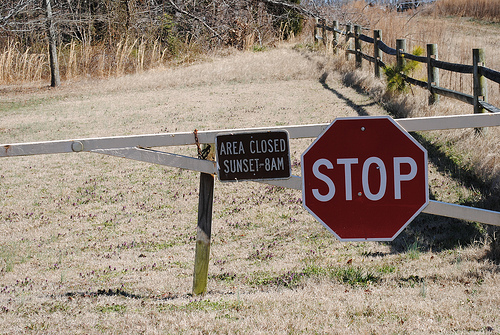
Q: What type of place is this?
A: It is a park.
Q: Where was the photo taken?
A: It was taken at the park.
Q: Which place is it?
A: It is a park.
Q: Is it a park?
A: Yes, it is a park.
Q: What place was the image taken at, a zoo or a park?
A: It was taken at a park.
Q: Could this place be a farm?
A: No, it is a park.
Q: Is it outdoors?
A: Yes, it is outdoors.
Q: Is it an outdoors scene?
A: Yes, it is outdoors.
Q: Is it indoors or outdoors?
A: It is outdoors.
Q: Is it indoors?
A: No, it is outdoors.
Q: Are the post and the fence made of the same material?
A: Yes, both the post and the fence are made of wood.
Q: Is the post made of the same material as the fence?
A: Yes, both the post and the fence are made of wood.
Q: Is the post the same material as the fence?
A: Yes, both the post and the fence are made of wood.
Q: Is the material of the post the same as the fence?
A: Yes, both the post and the fence are made of wood.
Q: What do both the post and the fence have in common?
A: The material, both the post and the fence are wooden.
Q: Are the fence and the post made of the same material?
A: Yes, both the fence and the post are made of wood.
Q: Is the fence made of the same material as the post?
A: Yes, both the fence and the post are made of wood.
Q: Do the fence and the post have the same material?
A: Yes, both the fence and the post are made of wood.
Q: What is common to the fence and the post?
A: The material, both the fence and the post are wooden.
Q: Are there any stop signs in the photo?
A: Yes, there is a stop sign.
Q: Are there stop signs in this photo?
A: Yes, there is a stop sign.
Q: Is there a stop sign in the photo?
A: Yes, there is a stop sign.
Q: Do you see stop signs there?
A: Yes, there is a stop sign.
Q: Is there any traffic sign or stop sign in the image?
A: Yes, there is a stop sign.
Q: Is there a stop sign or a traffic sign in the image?
A: Yes, there is a stop sign.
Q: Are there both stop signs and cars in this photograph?
A: No, there is a stop sign but no cars.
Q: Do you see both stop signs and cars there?
A: No, there is a stop sign but no cars.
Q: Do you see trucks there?
A: No, there are no trucks.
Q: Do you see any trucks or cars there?
A: No, there are no trucks or cars.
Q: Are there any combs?
A: No, there are no combs.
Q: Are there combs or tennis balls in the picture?
A: No, there are no combs or tennis balls.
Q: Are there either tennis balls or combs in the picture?
A: No, there are no combs or tennis balls.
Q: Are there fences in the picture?
A: Yes, there is a fence.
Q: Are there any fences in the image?
A: Yes, there is a fence.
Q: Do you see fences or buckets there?
A: Yes, there is a fence.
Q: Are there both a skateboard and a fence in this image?
A: No, there is a fence but no skateboards.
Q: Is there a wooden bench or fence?
A: Yes, there is a wood fence.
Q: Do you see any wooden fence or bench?
A: Yes, there is a wood fence.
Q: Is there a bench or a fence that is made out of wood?
A: Yes, the fence is made of wood.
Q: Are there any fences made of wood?
A: Yes, there is a fence that is made of wood.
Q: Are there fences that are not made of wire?
A: Yes, there is a fence that is made of wood.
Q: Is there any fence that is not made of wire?
A: Yes, there is a fence that is made of wood.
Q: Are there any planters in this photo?
A: No, there are no planters.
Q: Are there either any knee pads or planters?
A: No, there are no planters or knee pads.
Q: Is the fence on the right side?
A: Yes, the fence is on the right of the image.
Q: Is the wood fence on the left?
A: No, the fence is on the right of the image.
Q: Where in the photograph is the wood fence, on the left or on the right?
A: The fence is on the right of the image.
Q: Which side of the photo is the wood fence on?
A: The fence is on the right of the image.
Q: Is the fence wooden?
A: Yes, the fence is wooden.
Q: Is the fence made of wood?
A: Yes, the fence is made of wood.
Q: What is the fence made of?
A: The fence is made of wood.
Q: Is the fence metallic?
A: No, the fence is wooden.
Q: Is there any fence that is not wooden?
A: No, there is a fence but it is wooden.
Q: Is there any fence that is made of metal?
A: No, there is a fence but it is made of wood.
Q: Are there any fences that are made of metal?
A: No, there is a fence but it is made of wood.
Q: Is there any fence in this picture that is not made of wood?
A: No, there is a fence but it is made of wood.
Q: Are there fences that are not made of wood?
A: No, there is a fence but it is made of wood.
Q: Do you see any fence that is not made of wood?
A: No, there is a fence but it is made of wood.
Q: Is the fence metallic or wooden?
A: The fence is wooden.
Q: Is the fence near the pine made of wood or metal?
A: The fence is made of wood.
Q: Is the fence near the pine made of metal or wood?
A: The fence is made of wood.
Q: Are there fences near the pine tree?
A: Yes, there is a fence near the pine tree.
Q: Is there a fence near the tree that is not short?
A: Yes, there is a fence near the pine tree.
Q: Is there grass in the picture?
A: Yes, there is grass.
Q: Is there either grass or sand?
A: Yes, there is grass.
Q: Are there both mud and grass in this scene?
A: No, there is grass but no mud.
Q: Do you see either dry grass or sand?
A: Yes, there is dry grass.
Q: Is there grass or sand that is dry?
A: Yes, the grass is dry.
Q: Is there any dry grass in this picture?
A: Yes, there is dry grass.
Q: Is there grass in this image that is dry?
A: Yes, there is grass that is dry.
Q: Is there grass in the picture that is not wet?
A: Yes, there is dry grass.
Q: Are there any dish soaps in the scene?
A: No, there are no dish soaps.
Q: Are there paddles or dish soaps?
A: No, there are no dish soaps or paddles.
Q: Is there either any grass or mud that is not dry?
A: No, there is grass but it is dry.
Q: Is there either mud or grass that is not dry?
A: No, there is grass but it is dry.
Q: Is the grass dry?
A: Yes, the grass is dry.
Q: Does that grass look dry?
A: Yes, the grass is dry.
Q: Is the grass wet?
A: No, the grass is dry.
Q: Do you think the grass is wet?
A: No, the grass is dry.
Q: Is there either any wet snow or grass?
A: No, there is grass but it is dry.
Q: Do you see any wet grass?
A: No, there is grass but it is dry.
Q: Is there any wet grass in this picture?
A: No, there is grass but it is dry.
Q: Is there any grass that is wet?
A: No, there is grass but it is dry.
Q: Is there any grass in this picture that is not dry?
A: No, there is grass but it is dry.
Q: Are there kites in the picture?
A: No, there are no kites.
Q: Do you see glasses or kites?
A: No, there are no kites or glasses.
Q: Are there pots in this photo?
A: No, there are no pots.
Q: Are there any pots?
A: No, there are no pots.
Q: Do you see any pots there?
A: No, there are no pots.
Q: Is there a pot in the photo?
A: No, there are no pots.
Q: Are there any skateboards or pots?
A: No, there are no pots or skateboards.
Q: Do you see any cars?
A: No, there are no cars.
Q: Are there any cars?
A: No, there are no cars.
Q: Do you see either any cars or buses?
A: No, there are no cars or buses.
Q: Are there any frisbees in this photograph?
A: No, there are no frisbees.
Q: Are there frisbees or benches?
A: No, there are no frisbees or benches.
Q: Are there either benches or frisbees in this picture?
A: No, there are no frisbees or benches.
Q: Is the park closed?
A: Yes, the park is closed.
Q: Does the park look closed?
A: Yes, the park is closed.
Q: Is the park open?
A: No, the park is closed.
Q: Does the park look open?
A: No, the park is closed.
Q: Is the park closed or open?
A: The park is closed.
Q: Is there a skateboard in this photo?
A: No, there are no skateboards.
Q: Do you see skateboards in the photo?
A: No, there are no skateboards.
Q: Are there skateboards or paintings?
A: No, there are no skateboards or paintings.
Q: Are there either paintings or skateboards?
A: No, there are no skateboards or paintings.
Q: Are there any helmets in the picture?
A: No, there are no helmets.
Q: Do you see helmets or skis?
A: No, there are no helmets or skis.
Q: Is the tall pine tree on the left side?
A: Yes, the pine tree is on the left of the image.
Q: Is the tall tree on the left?
A: Yes, the pine tree is on the left of the image.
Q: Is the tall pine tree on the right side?
A: No, the pine is on the left of the image.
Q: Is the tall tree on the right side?
A: No, the pine is on the left of the image.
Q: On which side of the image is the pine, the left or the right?
A: The pine is on the left of the image.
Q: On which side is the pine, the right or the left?
A: The pine is on the left of the image.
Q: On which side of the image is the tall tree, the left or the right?
A: The pine is on the left of the image.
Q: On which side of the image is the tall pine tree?
A: The pine is on the left of the image.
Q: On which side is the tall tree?
A: The pine is on the left of the image.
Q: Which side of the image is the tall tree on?
A: The pine is on the left of the image.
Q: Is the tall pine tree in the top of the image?
A: Yes, the pine tree is in the top of the image.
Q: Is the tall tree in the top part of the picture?
A: Yes, the pine tree is in the top of the image.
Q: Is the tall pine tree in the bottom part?
A: No, the pine tree is in the top of the image.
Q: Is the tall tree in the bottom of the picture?
A: No, the pine tree is in the top of the image.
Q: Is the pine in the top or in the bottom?
A: The pine is in the top of the image.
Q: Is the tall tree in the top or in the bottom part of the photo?
A: The pine is in the top of the image.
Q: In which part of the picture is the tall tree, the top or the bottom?
A: The pine is in the top of the image.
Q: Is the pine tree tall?
A: Yes, the pine tree is tall.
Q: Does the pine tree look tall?
A: Yes, the pine tree is tall.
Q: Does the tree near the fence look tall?
A: Yes, the pine tree is tall.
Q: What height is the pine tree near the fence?
A: The pine tree is tall.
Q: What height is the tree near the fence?
A: The pine tree is tall.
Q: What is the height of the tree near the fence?
A: The pine tree is tall.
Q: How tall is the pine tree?
A: The pine tree is tall.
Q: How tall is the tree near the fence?
A: The pine tree is tall.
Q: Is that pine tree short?
A: No, the pine tree is tall.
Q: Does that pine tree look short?
A: No, the pine tree is tall.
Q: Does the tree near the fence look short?
A: No, the pine tree is tall.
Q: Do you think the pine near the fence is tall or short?
A: The pine tree is tall.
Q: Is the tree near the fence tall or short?
A: The pine tree is tall.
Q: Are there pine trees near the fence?
A: Yes, there is a pine tree near the fence.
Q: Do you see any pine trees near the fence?
A: Yes, there is a pine tree near the fence.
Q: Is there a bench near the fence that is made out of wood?
A: No, there is a pine tree near the fence.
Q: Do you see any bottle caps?
A: No, there are no bottle caps.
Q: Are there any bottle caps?
A: No, there are no bottle caps.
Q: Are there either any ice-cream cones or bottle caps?
A: No, there are no bottle caps or ice-cream cones.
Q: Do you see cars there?
A: No, there are no cars.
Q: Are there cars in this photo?
A: No, there are no cars.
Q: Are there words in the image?
A: Yes, there are words.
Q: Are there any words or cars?
A: Yes, there are words.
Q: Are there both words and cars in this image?
A: No, there are words but no cars.